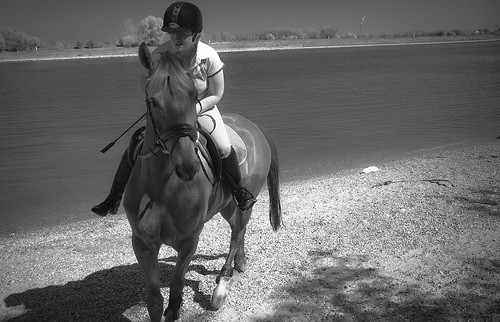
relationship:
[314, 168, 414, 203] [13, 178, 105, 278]
pebbles on beach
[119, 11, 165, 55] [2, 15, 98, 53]
trees in distance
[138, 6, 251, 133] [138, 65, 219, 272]
female on horse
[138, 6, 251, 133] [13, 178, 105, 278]
female on beach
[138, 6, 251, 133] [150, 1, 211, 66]
female wears helmet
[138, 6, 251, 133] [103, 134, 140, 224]
female in riding boots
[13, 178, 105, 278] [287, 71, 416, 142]
beach lighter than water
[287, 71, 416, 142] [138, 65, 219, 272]
water behind horse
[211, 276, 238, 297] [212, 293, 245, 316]
white by hoof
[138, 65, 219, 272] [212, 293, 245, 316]
horse has hoof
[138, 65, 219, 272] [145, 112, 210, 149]
horse wears bridle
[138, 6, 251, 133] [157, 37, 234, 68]
female wears white shirt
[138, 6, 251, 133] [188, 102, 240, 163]
female wears pants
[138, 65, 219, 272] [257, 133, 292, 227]
horse has tail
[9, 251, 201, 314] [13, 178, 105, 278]
shadow on beach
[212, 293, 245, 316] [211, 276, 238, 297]
hoof has white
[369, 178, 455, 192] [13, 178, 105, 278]
branch on beach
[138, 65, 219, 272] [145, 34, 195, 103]
horse has mane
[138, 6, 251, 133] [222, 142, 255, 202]
female wears riding boots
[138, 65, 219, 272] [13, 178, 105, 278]
horse on beach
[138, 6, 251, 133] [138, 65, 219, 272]
female rides horse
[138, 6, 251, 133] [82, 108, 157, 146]
female has crop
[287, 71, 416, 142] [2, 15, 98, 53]
water in distance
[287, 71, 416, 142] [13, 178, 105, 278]
water behind beach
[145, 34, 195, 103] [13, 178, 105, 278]
mane on beach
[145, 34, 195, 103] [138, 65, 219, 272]
mane on horse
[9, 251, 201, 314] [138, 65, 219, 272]
shadow of horse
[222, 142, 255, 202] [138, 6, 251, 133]
riding boots on female